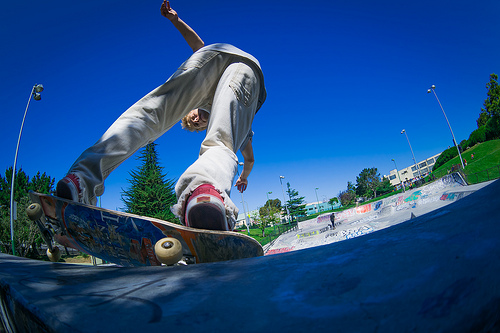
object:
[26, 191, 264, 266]
skateboard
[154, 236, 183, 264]
wheel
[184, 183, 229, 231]
shoe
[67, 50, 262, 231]
jeans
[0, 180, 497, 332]
wall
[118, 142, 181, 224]
tree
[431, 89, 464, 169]
pole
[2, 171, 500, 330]
skatepark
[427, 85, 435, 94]
lamp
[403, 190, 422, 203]
graffiti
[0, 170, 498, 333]
ground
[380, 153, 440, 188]
building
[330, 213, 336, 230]
person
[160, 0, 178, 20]
hand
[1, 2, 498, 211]
sky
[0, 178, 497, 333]
ramp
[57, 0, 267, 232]
guy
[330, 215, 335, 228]
clothing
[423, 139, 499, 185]
hill